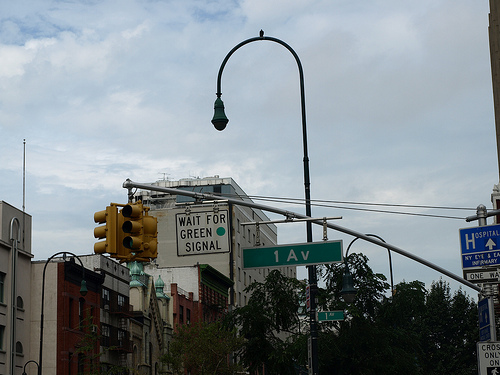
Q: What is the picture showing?
A: It is showing a town.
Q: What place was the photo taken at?
A: It was taken at the town.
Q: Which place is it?
A: It is a town.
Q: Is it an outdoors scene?
A: Yes, it is outdoors.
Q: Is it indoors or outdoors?
A: It is outdoors.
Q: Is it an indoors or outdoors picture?
A: It is outdoors.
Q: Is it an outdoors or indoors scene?
A: It is outdoors.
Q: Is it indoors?
A: No, it is outdoors.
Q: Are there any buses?
A: No, there are no buses.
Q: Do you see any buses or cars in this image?
A: No, there are no buses or cars.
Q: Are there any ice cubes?
A: No, there are no ice cubes.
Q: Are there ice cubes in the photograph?
A: No, there are no ice cubes.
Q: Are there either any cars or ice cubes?
A: No, there are no ice cubes or cars.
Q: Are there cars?
A: No, there are no cars.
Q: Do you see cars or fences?
A: No, there are no cars or fences.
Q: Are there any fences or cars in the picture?
A: No, there are no cars or fences.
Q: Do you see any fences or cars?
A: No, there are no cars or fences.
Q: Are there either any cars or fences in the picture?
A: No, there are no cars or fences.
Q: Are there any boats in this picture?
A: No, there are no boats.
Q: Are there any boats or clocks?
A: No, there are no boats or clocks.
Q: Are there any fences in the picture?
A: No, there are no fences.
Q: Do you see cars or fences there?
A: No, there are no fences or cars.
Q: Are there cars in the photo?
A: No, there are no cars.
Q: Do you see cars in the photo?
A: No, there are no cars.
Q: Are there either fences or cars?
A: No, there are no cars or fences.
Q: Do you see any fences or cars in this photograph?
A: No, there are no cars or fences.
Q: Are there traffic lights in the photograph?
A: Yes, there is a traffic light.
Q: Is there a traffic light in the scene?
A: Yes, there is a traffic light.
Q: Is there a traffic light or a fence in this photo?
A: Yes, there is a traffic light.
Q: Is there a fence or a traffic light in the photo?
A: Yes, there is a traffic light.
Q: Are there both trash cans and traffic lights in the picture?
A: No, there is a traffic light but no trash cans.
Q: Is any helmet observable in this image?
A: No, there are no helmets.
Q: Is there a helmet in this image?
A: No, there are no helmets.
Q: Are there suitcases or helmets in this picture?
A: No, there are no helmets or suitcases.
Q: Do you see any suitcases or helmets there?
A: No, there are no helmets or suitcases.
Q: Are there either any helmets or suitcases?
A: No, there are no helmets or suitcases.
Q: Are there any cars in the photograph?
A: No, there are no cars.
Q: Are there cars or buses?
A: No, there are no cars or buses.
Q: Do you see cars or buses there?
A: No, there are no cars or buses.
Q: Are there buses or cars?
A: No, there are no cars or buses.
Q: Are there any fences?
A: No, there are no fences.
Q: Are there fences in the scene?
A: No, there are no fences.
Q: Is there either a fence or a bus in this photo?
A: No, there are no fences or buses.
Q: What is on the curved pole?
A: The sign is on the pole.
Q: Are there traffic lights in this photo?
A: Yes, there is a traffic light.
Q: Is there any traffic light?
A: Yes, there is a traffic light.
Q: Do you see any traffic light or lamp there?
A: Yes, there is a traffic light.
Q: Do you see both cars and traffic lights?
A: No, there is a traffic light but no cars.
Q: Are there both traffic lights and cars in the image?
A: No, there is a traffic light but no cars.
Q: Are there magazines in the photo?
A: No, there are no magazines.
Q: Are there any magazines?
A: No, there are no magazines.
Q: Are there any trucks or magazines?
A: No, there are no magazines or trucks.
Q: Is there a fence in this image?
A: No, there are no fences.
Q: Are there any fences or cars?
A: No, there are no fences or cars.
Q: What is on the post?
A: The sign is on the post.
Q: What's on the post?
A: The sign is on the post.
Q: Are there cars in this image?
A: No, there are no cars.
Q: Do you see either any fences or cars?
A: No, there are no cars or fences.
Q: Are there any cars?
A: No, there are no cars.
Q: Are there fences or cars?
A: No, there are no cars or fences.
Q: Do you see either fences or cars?
A: No, there are no cars or fences.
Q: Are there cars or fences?
A: No, there are no cars or fences.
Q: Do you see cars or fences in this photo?
A: No, there are no cars or fences.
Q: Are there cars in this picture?
A: No, there are no cars.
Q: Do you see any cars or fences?
A: No, there are no cars or fences.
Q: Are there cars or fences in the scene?
A: No, there are no cars or fences.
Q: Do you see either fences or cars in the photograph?
A: No, there are no cars or fences.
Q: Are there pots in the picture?
A: No, there are no pots.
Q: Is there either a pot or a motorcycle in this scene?
A: No, there are no pots or motorcycles.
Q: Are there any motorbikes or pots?
A: No, there are no pots or motorbikes.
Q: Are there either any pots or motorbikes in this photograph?
A: No, there are no pots or motorbikes.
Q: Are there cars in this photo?
A: No, there are no cars.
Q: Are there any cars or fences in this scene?
A: No, there are no cars or fences.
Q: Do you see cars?
A: No, there are no cars.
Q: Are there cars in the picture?
A: No, there are no cars.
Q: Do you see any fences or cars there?
A: No, there are no cars or fences.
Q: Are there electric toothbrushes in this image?
A: No, there are no electric toothbrushes.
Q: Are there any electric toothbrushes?
A: No, there are no electric toothbrushes.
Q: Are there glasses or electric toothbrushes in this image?
A: No, there are no electric toothbrushes or glasses.